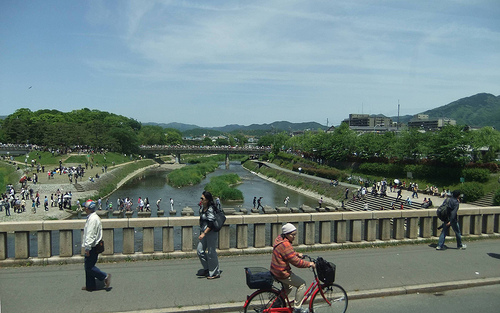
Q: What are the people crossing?
A: Bridge.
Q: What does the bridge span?
A: River.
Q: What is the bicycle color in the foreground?
A: Red.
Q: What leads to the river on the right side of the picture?
A: Steps.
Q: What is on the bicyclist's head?
A: Hat.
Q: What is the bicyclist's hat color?
A: White.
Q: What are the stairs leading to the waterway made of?
A: Cement.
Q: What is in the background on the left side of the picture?
A: Trees.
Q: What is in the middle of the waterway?
A: Island.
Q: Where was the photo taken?
A: Bridge.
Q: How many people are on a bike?
A: One.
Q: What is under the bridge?
A: River.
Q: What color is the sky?
A: Blue.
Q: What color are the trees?
A: Green.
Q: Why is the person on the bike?
A: Transportation.